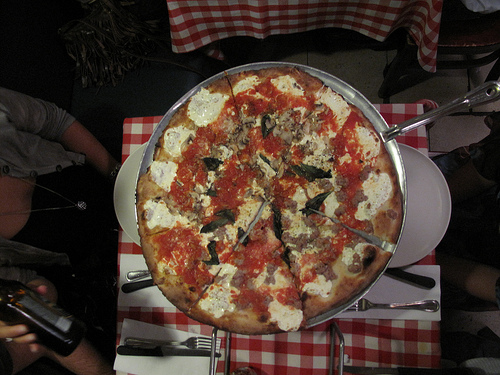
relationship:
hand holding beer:
[3, 279, 110, 373] [1, 277, 84, 356]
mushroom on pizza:
[207, 210, 233, 229] [129, 52, 423, 339]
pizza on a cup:
[133, 66, 404, 336] [135, 59, 405, 336]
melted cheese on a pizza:
[148, 82, 226, 179] [129, 52, 423, 339]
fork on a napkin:
[348, 296, 439, 314] [338, 263, 444, 318]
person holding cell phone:
[0, 277, 112, 374] [0, 277, 90, 355]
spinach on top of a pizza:
[289, 161, 334, 218] [133, 66, 404, 336]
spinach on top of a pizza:
[289, 161, 334, 218] [129, 52, 423, 339]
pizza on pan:
[133, 66, 404, 336] [342, 88, 357, 99]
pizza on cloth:
[133, 66, 404, 336] [113, 104, 445, 375]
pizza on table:
[133, 66, 404, 336] [116, 104, 441, 373]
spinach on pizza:
[289, 161, 334, 218] [133, 66, 404, 336]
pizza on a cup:
[129, 52, 423, 339] [135, 59, 405, 336]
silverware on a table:
[321, 74, 498, 208] [116, 104, 441, 373]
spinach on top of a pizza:
[289, 155, 339, 225] [133, 66, 404, 336]